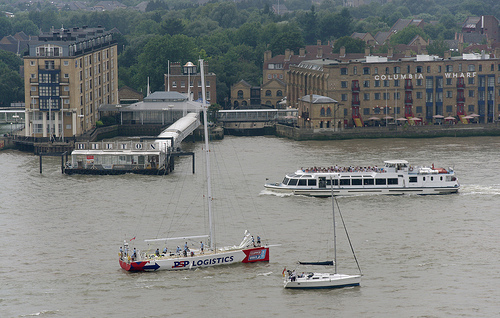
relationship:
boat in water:
[280, 271, 362, 291] [15, 174, 111, 313]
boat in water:
[260, 159, 460, 197] [15, 174, 111, 313]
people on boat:
[300, 165, 388, 176] [260, 159, 460, 197]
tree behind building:
[334, 36, 367, 55] [291, 41, 500, 133]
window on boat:
[387, 176, 399, 187] [260, 159, 460, 197]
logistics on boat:
[190, 256, 238, 266] [118, 238, 270, 273]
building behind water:
[291, 41, 500, 133] [15, 174, 111, 313]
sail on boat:
[325, 192, 369, 280] [280, 271, 362, 291]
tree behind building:
[319, 7, 360, 39] [291, 41, 500, 133]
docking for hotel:
[66, 117, 202, 176] [22, 23, 122, 138]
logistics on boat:
[190, 256, 238, 266] [118, 231, 271, 273]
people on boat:
[300, 165, 388, 176] [264, 160, 460, 197]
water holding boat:
[15, 174, 111, 313] [118, 238, 270, 273]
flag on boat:
[127, 229, 140, 247] [118, 238, 270, 273]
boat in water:
[118, 238, 270, 273] [15, 174, 111, 313]